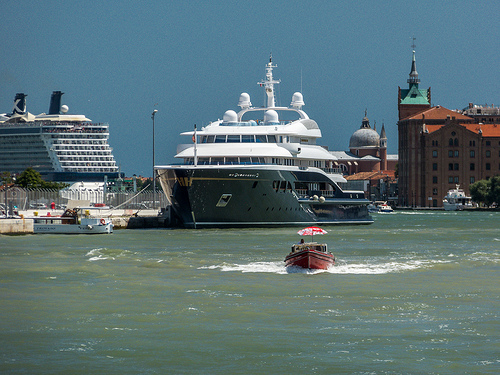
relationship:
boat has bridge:
[153, 52, 374, 230] [201, 125, 285, 141]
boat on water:
[282, 224, 339, 281] [85, 270, 497, 334]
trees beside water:
[468, 168, 500, 210] [4, 210, 496, 373]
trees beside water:
[18, 164, 48, 189] [4, 210, 496, 373]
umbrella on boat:
[298, 226, 328, 237] [277, 242, 354, 266]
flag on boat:
[184, 122, 204, 172] [153, 52, 374, 230]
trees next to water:
[463, 168, 498, 210] [20, 273, 157, 368]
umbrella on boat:
[298, 224, 326, 239] [170, 67, 411, 224]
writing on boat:
[230, 168, 263, 183] [153, 52, 374, 230]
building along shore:
[398, 32, 498, 205] [8, 195, 161, 237]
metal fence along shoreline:
[10, 179, 174, 219] [2, 185, 498, 214]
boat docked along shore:
[153, 52, 374, 230] [0, 180, 498, 210]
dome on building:
[345, 105, 383, 147] [318, 102, 398, 209]